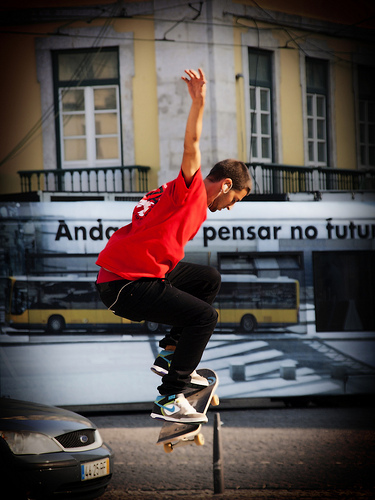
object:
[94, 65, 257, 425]
boy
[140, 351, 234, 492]
skateboard trick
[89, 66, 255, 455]
boy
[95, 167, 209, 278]
red shirt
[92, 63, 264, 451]
man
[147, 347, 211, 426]
shoes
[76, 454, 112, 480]
car/license plate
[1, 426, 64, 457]
car headlight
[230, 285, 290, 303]
bus windows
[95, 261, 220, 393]
black pants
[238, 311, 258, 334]
bus/back tire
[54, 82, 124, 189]
window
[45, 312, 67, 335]
front/bus tire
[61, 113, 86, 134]
glass pane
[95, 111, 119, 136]
small pane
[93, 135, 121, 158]
small pane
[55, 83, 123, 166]
window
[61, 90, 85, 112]
glass pane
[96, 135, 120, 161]
glass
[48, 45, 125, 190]
window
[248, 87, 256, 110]
glass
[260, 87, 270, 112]
glass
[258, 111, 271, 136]
glass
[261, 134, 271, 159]
glass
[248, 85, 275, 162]
window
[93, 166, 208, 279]
shirt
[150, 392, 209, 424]
shoe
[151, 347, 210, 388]
shoe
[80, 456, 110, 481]
license plate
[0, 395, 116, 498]
car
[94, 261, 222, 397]
pants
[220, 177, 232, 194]
ear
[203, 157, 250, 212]
head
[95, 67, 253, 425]
man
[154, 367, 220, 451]
skateboard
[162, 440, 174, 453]
wheel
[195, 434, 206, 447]
wheel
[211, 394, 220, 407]
wheel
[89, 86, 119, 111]
glass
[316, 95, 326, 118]
glass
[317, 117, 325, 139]
glass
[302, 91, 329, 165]
window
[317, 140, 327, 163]
glass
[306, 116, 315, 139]
glass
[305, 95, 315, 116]
glass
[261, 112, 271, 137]
glass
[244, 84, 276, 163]
window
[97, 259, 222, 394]
jeans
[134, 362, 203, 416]
shoe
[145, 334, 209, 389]
shoe